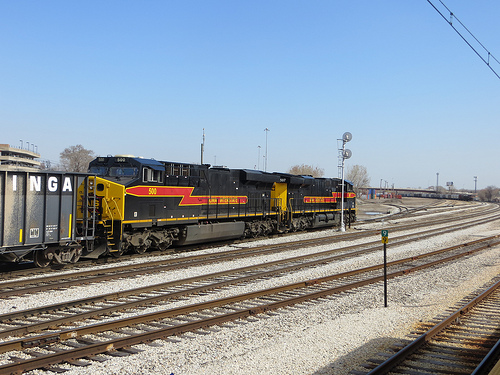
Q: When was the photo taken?
A: A sunny day.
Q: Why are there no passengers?
A: It's a freight train.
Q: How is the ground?
A: Rocky.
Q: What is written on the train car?
A: Inga.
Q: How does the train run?
A: On tracks.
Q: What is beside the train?
A: Signals.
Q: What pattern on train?
A: Zig zag.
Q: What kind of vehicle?
A: Train.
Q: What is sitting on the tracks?
A: Train.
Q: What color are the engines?
A: Yellow, black, red.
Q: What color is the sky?
A: Blue.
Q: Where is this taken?
A: Train tracks.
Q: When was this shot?
A: Daytime.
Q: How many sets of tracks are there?
A: 5.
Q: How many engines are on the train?
A: 2.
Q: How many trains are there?
A: 1.